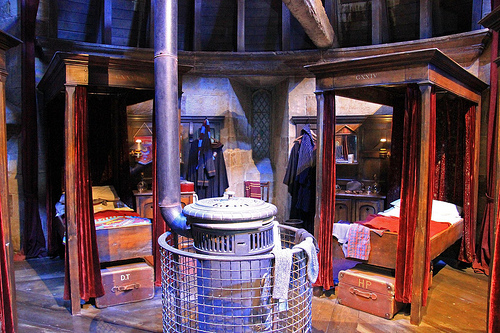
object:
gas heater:
[181, 193, 281, 330]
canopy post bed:
[37, 49, 196, 315]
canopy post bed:
[303, 46, 495, 325]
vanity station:
[334, 114, 393, 242]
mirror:
[335, 135, 357, 163]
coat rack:
[295, 133, 318, 142]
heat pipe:
[152, 0, 190, 235]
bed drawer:
[93, 262, 155, 310]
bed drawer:
[334, 262, 405, 320]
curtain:
[77, 86, 105, 301]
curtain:
[313, 93, 337, 289]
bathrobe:
[295, 124, 315, 177]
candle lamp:
[135, 138, 143, 150]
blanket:
[92, 209, 140, 220]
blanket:
[361, 214, 453, 240]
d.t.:
[120, 274, 125, 281]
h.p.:
[358, 278, 371, 288]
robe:
[186, 141, 230, 199]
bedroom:
[3, 2, 499, 325]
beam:
[282, 1, 337, 49]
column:
[63, 64, 102, 309]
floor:
[17, 257, 499, 332]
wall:
[40, 49, 398, 276]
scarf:
[244, 181, 261, 200]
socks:
[291, 240, 319, 285]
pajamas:
[345, 223, 373, 261]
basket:
[155, 224, 313, 333]